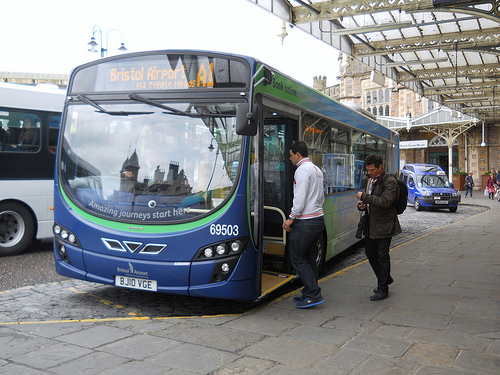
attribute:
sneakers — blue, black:
[295, 291, 328, 308]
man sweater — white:
[283, 134, 348, 312]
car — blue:
[393, 157, 484, 215]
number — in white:
[207, 220, 244, 238]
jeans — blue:
[281, 202, 325, 297]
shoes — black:
[362, 282, 397, 301]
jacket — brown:
[360, 172, 403, 242]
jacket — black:
[365, 177, 403, 239]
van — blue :
[398, 150, 469, 217]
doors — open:
[258, 110, 293, 269]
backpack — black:
[385, 167, 412, 231]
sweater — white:
[282, 159, 328, 223]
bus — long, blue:
[50, 35, 410, 313]